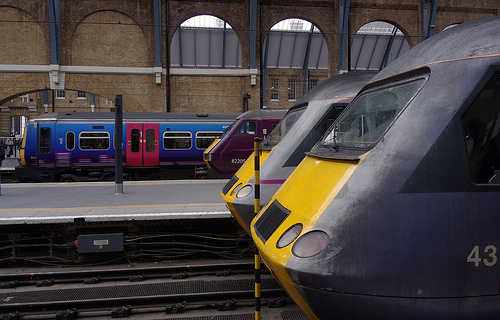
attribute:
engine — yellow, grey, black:
[248, 19, 498, 319]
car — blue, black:
[14, 115, 238, 179]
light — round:
[289, 227, 331, 259]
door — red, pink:
[125, 121, 161, 170]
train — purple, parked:
[201, 106, 298, 174]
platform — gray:
[1, 178, 231, 219]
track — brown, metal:
[1, 257, 278, 311]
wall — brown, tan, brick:
[2, 0, 499, 115]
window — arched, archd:
[161, 11, 244, 70]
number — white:
[467, 242, 497, 268]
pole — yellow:
[252, 133, 266, 319]